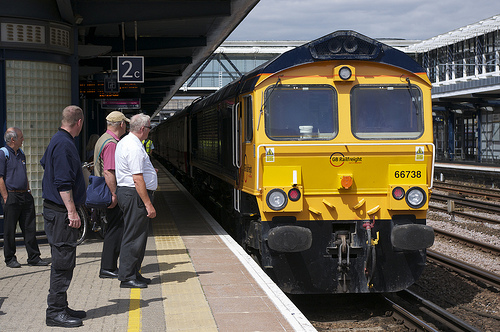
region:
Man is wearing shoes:
[46, 303, 88, 328]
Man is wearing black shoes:
[41, 298, 93, 328]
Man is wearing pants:
[40, 200, 77, 314]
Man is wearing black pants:
[43, 200, 83, 314]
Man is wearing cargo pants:
[38, 202, 78, 314]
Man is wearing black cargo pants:
[37, 203, 84, 316]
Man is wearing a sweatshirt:
[35, 125, 87, 210]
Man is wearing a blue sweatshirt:
[35, 125, 89, 212]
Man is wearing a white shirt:
[112, 130, 164, 189]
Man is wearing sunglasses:
[137, 123, 155, 130]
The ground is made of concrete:
[151, 242, 247, 312]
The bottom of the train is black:
[278, 225, 431, 291]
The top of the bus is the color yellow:
[264, 148, 418, 195]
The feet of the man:
[35, 299, 91, 328]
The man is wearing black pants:
[38, 205, 87, 312]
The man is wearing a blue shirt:
[38, 127, 90, 216]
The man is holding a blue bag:
[81, 135, 120, 210]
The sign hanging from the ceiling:
[111, 20, 148, 89]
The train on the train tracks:
[147, 26, 464, 309]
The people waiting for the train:
[0, 110, 170, 328]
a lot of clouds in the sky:
[229, 1, 498, 42]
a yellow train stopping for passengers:
[145, 25, 439, 300]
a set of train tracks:
[383, 178, 498, 330]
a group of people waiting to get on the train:
[0, 105, 163, 330]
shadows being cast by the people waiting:
[72, 240, 218, 323]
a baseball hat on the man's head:
[105, 110, 130, 124]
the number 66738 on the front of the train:
[393, 167, 421, 179]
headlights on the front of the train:
[265, 180, 428, 212]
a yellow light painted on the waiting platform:
[124, 267, 144, 330]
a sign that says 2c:
[116, 54, 146, 82]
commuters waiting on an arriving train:
[25, 5, 453, 311]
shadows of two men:
[145, 255, 210, 287]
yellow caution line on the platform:
[115, 285, 150, 325]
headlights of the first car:
[265, 175, 425, 215]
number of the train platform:
[111, 50, 146, 81]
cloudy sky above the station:
[267, 0, 442, 25]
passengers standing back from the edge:
[1, 95, 226, 310]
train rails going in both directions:
[435, 167, 495, 327]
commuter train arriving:
[155, 25, 445, 290]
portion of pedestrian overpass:
[190, 71, 220, 88]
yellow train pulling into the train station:
[151, 27, 435, 307]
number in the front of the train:
[391, 168, 423, 180]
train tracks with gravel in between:
[321, 172, 498, 330]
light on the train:
[335, 66, 354, 80]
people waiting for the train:
[0, 103, 159, 329]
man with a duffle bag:
[87, 110, 129, 279]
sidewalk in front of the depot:
[142, 158, 315, 330]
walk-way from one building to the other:
[168, 39, 412, 106]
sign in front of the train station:
[116, 53, 145, 84]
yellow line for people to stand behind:
[126, 283, 143, 330]